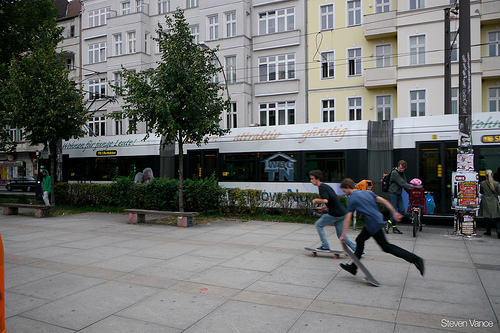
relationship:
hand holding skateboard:
[335, 233, 348, 240] [336, 238, 380, 291]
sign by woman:
[452, 174, 481, 206] [468, 161, 498, 226]